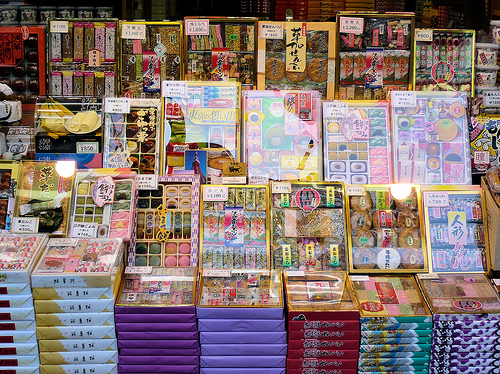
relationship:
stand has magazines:
[0, 1, 498, 370] [104, 97, 158, 190]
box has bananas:
[413, 29, 475, 98] [259, 22, 334, 99]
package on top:
[119, 23, 184, 100] [259, 25, 334, 99]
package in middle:
[119, 23, 184, 100] [241, 89, 324, 180]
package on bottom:
[119, 23, 184, 100] [269, 181, 350, 271]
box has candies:
[413, 29, 475, 98] [37, 97, 101, 142]